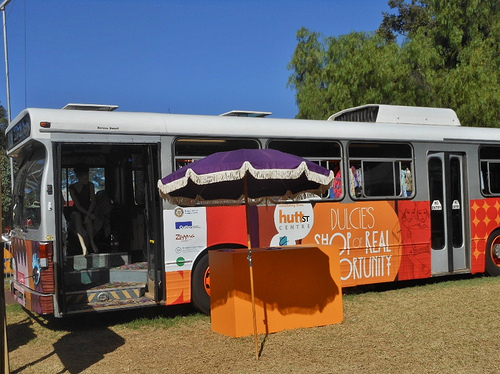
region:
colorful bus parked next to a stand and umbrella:
[20, 97, 498, 317]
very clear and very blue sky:
[37, 10, 265, 95]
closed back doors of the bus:
[423, 144, 473, 280]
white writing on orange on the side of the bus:
[318, 210, 397, 286]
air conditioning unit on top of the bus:
[328, 105, 455, 127]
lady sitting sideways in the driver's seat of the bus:
[64, 163, 104, 255]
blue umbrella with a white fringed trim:
[137, 145, 342, 209]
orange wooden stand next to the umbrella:
[204, 245, 344, 340]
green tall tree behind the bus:
[280, 6, 495, 104]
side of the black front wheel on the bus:
[190, 249, 210, 316]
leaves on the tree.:
[333, 49, 353, 75]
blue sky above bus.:
[138, 48, 186, 59]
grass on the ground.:
[430, 333, 460, 350]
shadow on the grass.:
[78, 337, 103, 349]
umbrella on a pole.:
[217, 156, 278, 161]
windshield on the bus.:
[31, 170, 39, 200]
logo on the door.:
[432, 196, 442, 211]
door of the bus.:
[442, 160, 464, 196]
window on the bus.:
[366, 168, 386, 190]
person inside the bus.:
[68, 170, 93, 252]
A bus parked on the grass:
[0, 97, 499, 322]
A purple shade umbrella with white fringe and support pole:
[155, 138, 337, 361]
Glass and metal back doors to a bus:
[425, 140, 470, 270]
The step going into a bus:
[55, 261, 162, 312]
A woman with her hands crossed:
[62, 160, 97, 257]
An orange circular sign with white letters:
[297, 200, 402, 285]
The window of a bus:
[347, 140, 417, 200]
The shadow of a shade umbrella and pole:
[200, 237, 351, 332]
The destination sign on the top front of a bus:
[0, 108, 34, 154]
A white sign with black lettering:
[432, 197, 442, 214]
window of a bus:
[12, 154, 28, 223]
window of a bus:
[19, 158, 54, 228]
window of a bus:
[176, 131, 206, 158]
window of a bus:
[210, 133, 260, 165]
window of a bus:
[272, 131, 310, 161]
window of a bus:
[307, 129, 339, 163]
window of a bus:
[362, 160, 399, 198]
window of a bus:
[423, 156, 465, 247]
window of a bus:
[478, 145, 497, 155]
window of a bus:
[476, 158, 495, 190]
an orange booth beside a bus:
[205, 236, 345, 338]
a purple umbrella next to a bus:
[155, 145, 331, 205]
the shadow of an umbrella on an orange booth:
[209, 247, 339, 316]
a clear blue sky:
[1, 0, 430, 119]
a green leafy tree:
[290, 0, 499, 126]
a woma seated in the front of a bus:
[67, 158, 101, 254]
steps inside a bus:
[56, 248, 144, 310]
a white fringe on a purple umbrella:
[157, 160, 332, 206]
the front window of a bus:
[11, 144, 45, 230]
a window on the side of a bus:
[344, 139, 417, 200]